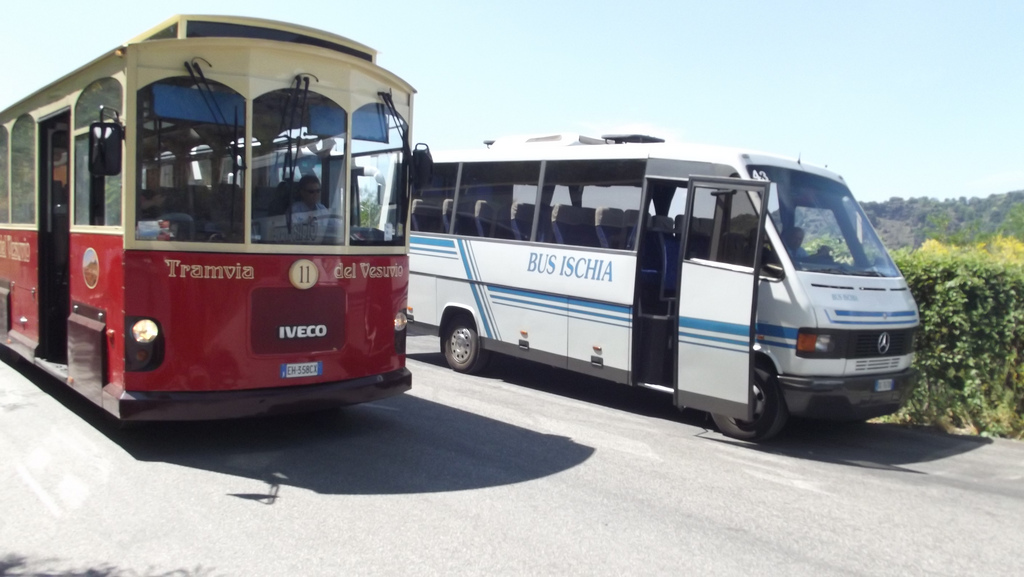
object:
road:
[0, 355, 1022, 577]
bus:
[0, 14, 416, 423]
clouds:
[0, 0, 1024, 204]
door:
[673, 174, 769, 423]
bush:
[900, 248, 1024, 437]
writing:
[164, 260, 254, 280]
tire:
[441, 314, 490, 373]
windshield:
[132, 77, 409, 248]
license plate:
[279, 361, 323, 379]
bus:
[408, 132, 923, 442]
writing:
[528, 252, 615, 283]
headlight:
[131, 318, 159, 344]